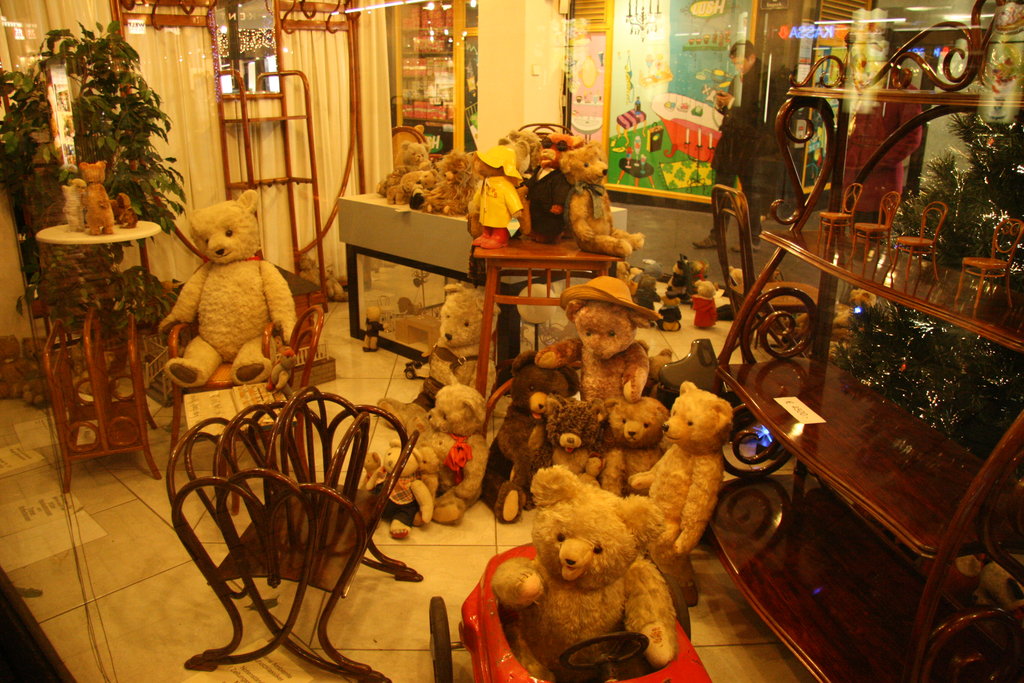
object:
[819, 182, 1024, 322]
chairs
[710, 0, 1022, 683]
shelf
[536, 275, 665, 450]
teddy bear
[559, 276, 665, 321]
hat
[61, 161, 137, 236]
statues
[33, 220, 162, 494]
stand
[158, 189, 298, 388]
teddy bear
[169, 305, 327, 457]
chair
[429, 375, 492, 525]
teddy bear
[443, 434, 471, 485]
neck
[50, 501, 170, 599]
tile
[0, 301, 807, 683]
floor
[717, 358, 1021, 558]
wood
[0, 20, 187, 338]
leaves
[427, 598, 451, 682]
tire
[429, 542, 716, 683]
car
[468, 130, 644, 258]
teddy bears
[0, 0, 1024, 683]
store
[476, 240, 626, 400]
table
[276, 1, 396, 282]
curtain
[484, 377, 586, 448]
teddy bear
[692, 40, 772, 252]
man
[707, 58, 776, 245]
black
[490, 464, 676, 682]
toy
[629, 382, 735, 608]
toy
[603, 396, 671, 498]
toy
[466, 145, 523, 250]
toy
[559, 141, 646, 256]
toy